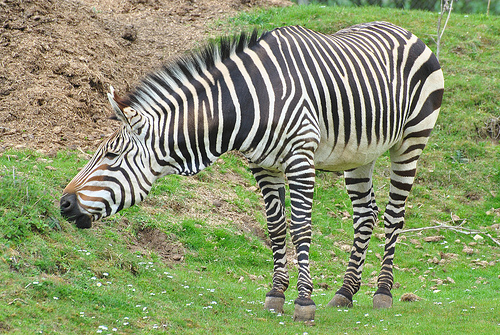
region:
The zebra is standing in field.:
[150, 39, 462, 316]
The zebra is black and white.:
[91, 69, 433, 310]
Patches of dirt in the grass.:
[28, 193, 295, 323]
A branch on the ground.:
[406, 205, 476, 268]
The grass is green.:
[18, 203, 438, 320]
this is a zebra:
[46, 3, 480, 328]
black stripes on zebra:
[252, 43, 394, 129]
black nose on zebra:
[46, 180, 78, 217]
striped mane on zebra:
[113, 12, 268, 150]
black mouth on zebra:
[65, 203, 87, 228]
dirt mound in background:
[8, 0, 203, 181]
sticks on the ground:
[377, 188, 499, 299]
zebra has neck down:
[30, 14, 444, 329]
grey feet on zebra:
[249, 271, 426, 333]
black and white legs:
[219, 151, 425, 299]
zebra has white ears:
[95, 61, 134, 141]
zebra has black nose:
[65, 173, 88, 230]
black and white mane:
[101, 34, 250, 114]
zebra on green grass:
[58, 68, 436, 319]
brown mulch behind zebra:
[0, 34, 164, 124]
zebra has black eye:
[85, 136, 127, 177]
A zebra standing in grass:
[56, 18, 446, 308]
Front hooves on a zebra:
[257, 296, 317, 323]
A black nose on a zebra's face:
[57, 191, 78, 220]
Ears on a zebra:
[101, 83, 131, 130]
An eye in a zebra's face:
[100, 150, 123, 163]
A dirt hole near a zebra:
[134, 224, 169, 259]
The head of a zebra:
[61, 85, 163, 228]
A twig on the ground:
[402, 221, 469, 235]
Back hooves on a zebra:
[334, 281, 389, 309]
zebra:
[37, 13, 448, 288]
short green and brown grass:
[443, 286, 483, 331]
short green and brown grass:
[182, 236, 220, 276]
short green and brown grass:
[143, 288, 195, 330]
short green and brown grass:
[96, 256, 136, 283]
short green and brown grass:
[42, 279, 100, 317]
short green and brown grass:
[445, 185, 466, 223]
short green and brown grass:
[455, 128, 489, 165]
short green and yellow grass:
[153, 272, 193, 316]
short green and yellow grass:
[450, 278, 475, 296]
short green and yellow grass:
[199, 268, 231, 312]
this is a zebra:
[28, 23, 455, 283]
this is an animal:
[49, 9, 388, 275]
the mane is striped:
[105, 35, 269, 129]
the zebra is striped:
[115, 56, 358, 181]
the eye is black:
[89, 139, 146, 158]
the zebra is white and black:
[92, 18, 391, 184]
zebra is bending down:
[55, 17, 447, 322]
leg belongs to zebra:
[280, 124, 320, 324]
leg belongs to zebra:
[251, 161, 290, 315]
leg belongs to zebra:
[327, 153, 379, 310]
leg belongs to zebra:
[369, 110, 431, 307]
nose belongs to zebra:
[58, 194, 75, 220]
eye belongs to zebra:
[102, 149, 119, 161]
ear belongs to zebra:
[107, 88, 140, 128]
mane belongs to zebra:
[124, 25, 265, 113]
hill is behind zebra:
[0, 0, 499, 192]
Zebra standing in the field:
[36, 17, 463, 320]